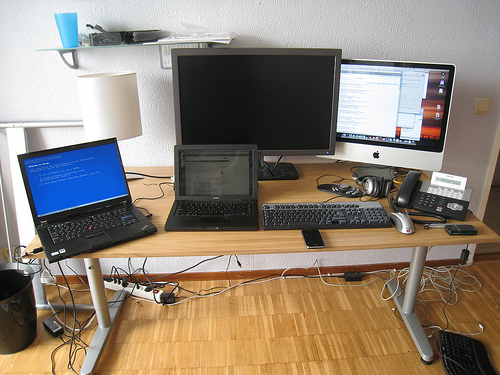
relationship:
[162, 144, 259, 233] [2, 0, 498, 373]
notebook in office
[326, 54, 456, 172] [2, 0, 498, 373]
computer in office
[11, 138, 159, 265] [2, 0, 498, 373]
laptop in office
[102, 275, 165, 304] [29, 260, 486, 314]
power strip has wires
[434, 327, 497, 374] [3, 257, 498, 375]
keyboard on floor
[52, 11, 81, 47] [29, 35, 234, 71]
glass on shelf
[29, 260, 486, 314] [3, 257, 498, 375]
wires on floor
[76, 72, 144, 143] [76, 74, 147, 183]
lampshade on lamp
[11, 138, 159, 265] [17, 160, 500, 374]
laptop on desk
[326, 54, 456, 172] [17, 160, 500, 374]
computer on desk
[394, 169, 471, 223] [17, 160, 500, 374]
phone on desk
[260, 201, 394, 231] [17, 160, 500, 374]
keyboard on desk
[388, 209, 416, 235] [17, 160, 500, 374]
mouse on desk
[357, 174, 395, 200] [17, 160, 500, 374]
headphone on desk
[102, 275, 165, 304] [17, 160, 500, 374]
power strip under desk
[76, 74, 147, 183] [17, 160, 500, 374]
lamp on desk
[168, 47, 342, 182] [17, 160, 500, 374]
monitor on desk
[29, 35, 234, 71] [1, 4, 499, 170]
shelf on wall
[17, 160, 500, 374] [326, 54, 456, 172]
desk has computer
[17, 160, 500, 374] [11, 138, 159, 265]
desk has laptop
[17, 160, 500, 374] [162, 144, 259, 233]
desk has notebook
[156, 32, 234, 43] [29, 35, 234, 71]
paper on shelf